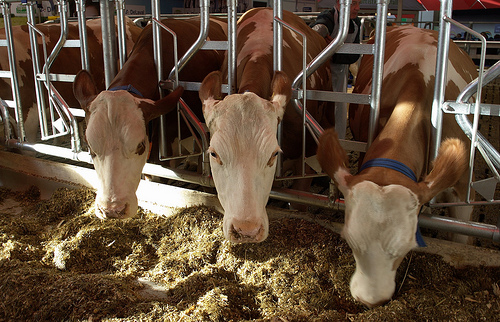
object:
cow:
[75, 15, 230, 224]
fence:
[0, 1, 500, 242]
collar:
[360, 158, 420, 181]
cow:
[196, 7, 333, 245]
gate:
[3, 0, 45, 143]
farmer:
[312, 0, 366, 90]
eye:
[132, 142, 150, 156]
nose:
[223, 216, 273, 245]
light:
[24, 107, 187, 221]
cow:
[316, 21, 483, 306]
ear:
[317, 128, 348, 188]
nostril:
[118, 202, 136, 216]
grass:
[0, 189, 500, 321]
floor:
[116, 275, 179, 304]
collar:
[107, 84, 149, 100]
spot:
[266, 148, 280, 168]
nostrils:
[228, 222, 244, 241]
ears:
[271, 68, 292, 107]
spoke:
[149, 0, 165, 162]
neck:
[354, 112, 435, 187]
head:
[69, 61, 159, 222]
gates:
[113, 0, 172, 162]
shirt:
[309, 5, 362, 64]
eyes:
[87, 143, 100, 156]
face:
[204, 91, 285, 248]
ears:
[72, 69, 101, 113]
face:
[85, 91, 151, 220]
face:
[344, 181, 422, 308]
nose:
[96, 199, 132, 218]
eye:
[206, 150, 222, 163]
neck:
[104, 60, 167, 125]